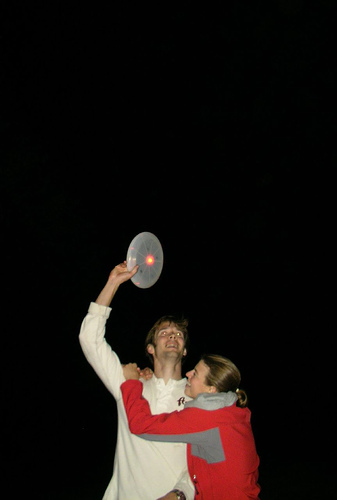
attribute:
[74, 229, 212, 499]
man — young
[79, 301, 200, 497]
shirt — white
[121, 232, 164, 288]
frisbee — plastic, white, glowing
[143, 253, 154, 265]
light — red, orange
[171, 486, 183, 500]
watch — metal, black, silver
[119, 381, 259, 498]
clothing — partially grey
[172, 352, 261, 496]
woman — grey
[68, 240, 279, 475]
couple — hugging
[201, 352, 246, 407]
hair — pony tailed, pulled back, brown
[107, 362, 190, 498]
shirt — white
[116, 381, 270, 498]
shirt — red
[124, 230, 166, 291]
frisbee — light-up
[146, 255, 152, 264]
light — red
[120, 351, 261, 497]
woman — young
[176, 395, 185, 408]
logo — red 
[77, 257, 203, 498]
man — looking up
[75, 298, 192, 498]
shirt — white 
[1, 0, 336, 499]
sky — black, deep, rich, night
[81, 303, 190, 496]
shirt — white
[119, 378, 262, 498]
hoodie — red, gray